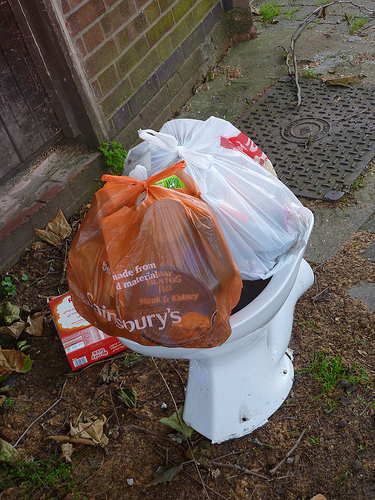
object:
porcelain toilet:
[116, 206, 318, 444]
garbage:
[66, 112, 309, 352]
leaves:
[1, 305, 107, 498]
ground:
[0, 0, 371, 495]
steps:
[3, 139, 103, 270]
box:
[47, 290, 131, 371]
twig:
[277, 0, 373, 109]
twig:
[308, 283, 329, 300]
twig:
[267, 424, 310, 475]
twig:
[146, 439, 224, 497]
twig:
[12, 369, 66, 445]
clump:
[347, 12, 372, 36]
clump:
[257, 0, 278, 24]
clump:
[297, 349, 372, 411]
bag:
[65, 159, 242, 349]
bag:
[121, 114, 311, 279]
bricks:
[60, 1, 246, 154]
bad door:
[0, 0, 105, 184]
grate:
[233, 71, 373, 207]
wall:
[63, 6, 234, 155]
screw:
[242, 417, 247, 422]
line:
[75, 11, 107, 35]